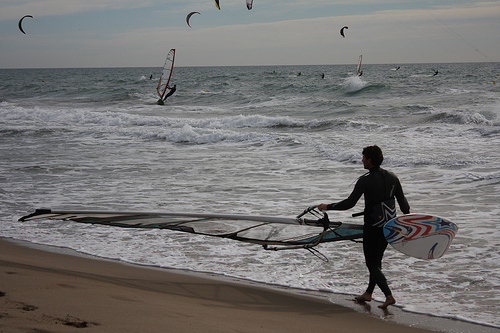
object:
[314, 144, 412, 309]
person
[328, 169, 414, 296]
wetsuit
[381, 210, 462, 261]
board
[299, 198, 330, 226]
handle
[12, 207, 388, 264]
sail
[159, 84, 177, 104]
person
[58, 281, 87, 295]
footprints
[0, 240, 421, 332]
beach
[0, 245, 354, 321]
shadow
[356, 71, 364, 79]
person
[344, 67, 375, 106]
wave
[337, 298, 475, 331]
water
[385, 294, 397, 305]
heel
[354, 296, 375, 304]
feet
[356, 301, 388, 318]
shadow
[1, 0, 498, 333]
image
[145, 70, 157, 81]
people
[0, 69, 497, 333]
ocean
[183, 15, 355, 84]
strings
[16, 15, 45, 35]
kites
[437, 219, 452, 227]
star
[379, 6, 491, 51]
clouds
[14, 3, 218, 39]
sky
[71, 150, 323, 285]
surf